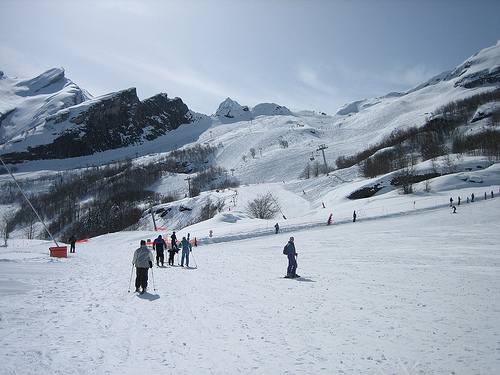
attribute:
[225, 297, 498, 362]
snow — white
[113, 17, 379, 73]
sky — blue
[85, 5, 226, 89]
clouds — white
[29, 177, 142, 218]
trees — green